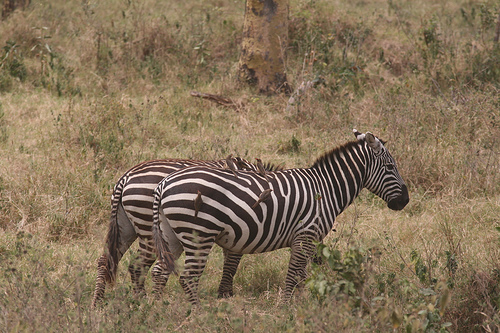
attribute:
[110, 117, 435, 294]
zebras — standing, black, facing, walking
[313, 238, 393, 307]
grass — long, tan, a lot, green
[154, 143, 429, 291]
zebra — in front, striped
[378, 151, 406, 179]
eye — black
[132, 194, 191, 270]
tail — hanging, striped, long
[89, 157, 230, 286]
zebra — behind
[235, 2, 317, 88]
tree — light brown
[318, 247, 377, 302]
weeds — green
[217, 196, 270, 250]
stripes — black